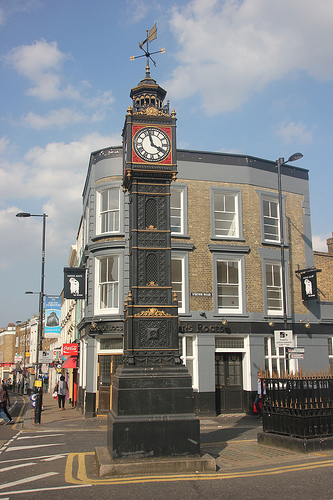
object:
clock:
[130, 120, 173, 168]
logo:
[62, 343, 80, 355]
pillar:
[107, 178, 202, 457]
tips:
[256, 365, 332, 378]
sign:
[274, 329, 294, 346]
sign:
[44, 294, 61, 337]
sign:
[63, 266, 86, 301]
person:
[55, 375, 69, 412]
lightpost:
[34, 213, 49, 424]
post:
[33, 213, 48, 423]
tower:
[106, 22, 200, 458]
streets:
[0, 417, 332, 499]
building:
[91, 143, 126, 415]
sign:
[62, 342, 80, 355]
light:
[15, 212, 47, 424]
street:
[0, 385, 30, 499]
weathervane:
[129, 22, 167, 76]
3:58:
[146, 128, 167, 156]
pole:
[35, 213, 49, 425]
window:
[211, 188, 240, 236]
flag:
[63, 265, 86, 300]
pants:
[58, 393, 66, 408]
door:
[96, 351, 123, 413]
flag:
[44, 294, 62, 338]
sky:
[0, 1, 332, 328]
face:
[133, 124, 168, 163]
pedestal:
[93, 444, 217, 475]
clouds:
[2, 2, 332, 255]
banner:
[300, 272, 321, 300]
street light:
[16, 211, 49, 426]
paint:
[0, 430, 92, 498]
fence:
[260, 368, 332, 439]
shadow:
[199, 415, 263, 460]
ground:
[0, 412, 332, 499]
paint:
[64, 449, 332, 484]